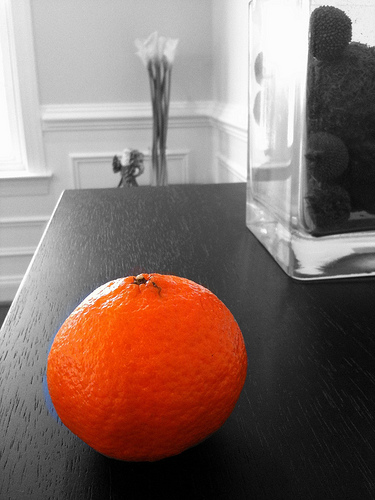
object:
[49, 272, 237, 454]
color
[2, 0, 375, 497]
picture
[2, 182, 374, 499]
table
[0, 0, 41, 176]
window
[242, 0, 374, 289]
vase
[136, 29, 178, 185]
flowers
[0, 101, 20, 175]
sulight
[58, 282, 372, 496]
shadows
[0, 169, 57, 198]
window sill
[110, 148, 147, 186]
flower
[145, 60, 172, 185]
stems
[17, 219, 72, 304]
light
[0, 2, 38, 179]
curtains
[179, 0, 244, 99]
wallpaper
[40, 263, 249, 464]
fruit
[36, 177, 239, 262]
panels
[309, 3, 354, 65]
balls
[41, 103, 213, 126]
trim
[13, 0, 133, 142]
wall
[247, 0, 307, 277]
reflection